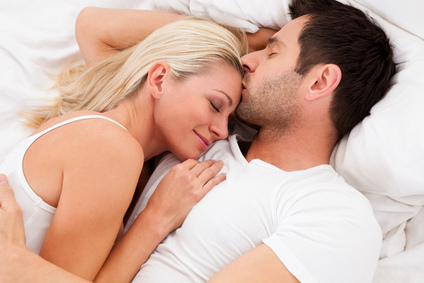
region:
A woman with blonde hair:
[19, 19, 237, 163]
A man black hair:
[242, 0, 396, 164]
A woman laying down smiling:
[0, 21, 242, 281]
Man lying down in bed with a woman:
[0, 0, 422, 281]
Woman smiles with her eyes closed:
[142, 35, 241, 160]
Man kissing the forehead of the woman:
[234, 1, 392, 169]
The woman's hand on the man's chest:
[142, 155, 228, 230]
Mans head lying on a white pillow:
[288, 0, 421, 206]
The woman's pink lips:
[182, 120, 212, 156]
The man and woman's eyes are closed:
[198, 32, 294, 116]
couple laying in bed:
[1, 1, 389, 282]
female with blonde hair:
[15, 13, 379, 279]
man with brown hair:
[43, 1, 380, 280]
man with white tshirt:
[16, 1, 380, 281]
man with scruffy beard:
[34, 1, 379, 269]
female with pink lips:
[20, 0, 379, 279]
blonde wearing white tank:
[20, 1, 378, 226]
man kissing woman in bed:
[9, 8, 397, 279]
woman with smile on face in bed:
[11, 7, 385, 274]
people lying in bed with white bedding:
[13, 2, 407, 281]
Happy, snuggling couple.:
[13, 10, 391, 281]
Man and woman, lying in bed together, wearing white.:
[29, 8, 380, 282]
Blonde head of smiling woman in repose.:
[77, 35, 241, 163]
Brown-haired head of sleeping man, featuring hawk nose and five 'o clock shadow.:
[237, 5, 370, 154]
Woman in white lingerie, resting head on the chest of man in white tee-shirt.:
[15, 13, 389, 274]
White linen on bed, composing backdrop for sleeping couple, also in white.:
[3, 6, 422, 274]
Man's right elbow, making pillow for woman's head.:
[73, 7, 248, 163]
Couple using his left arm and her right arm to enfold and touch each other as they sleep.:
[1, 179, 304, 281]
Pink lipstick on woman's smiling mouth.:
[191, 127, 219, 155]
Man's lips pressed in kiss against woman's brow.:
[233, 67, 261, 100]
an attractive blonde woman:
[5, 10, 232, 281]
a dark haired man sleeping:
[160, 1, 407, 277]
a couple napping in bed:
[33, 1, 408, 261]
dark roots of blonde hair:
[32, 27, 262, 135]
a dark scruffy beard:
[232, 67, 302, 140]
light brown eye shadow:
[199, 85, 234, 113]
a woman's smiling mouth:
[182, 119, 211, 156]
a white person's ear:
[302, 57, 344, 100]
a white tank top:
[3, 103, 144, 272]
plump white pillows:
[282, 4, 417, 275]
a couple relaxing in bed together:
[16, 2, 398, 281]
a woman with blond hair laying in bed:
[33, 11, 241, 282]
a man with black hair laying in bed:
[228, 4, 406, 282]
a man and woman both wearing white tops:
[8, 7, 402, 282]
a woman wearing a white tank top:
[12, 8, 237, 280]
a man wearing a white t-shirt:
[235, 2, 422, 281]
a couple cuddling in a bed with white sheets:
[60, 3, 414, 281]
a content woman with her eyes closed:
[6, 4, 239, 282]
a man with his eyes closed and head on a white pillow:
[228, 8, 409, 281]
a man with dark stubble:
[220, 2, 393, 282]